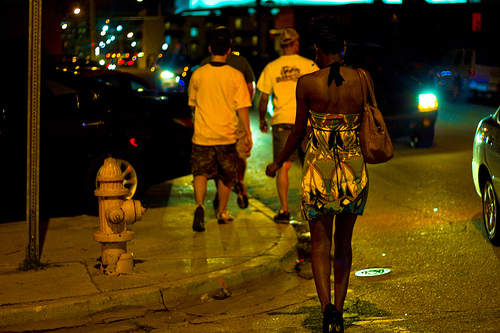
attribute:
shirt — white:
[183, 59, 251, 148]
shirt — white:
[256, 52, 323, 129]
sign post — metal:
[19, 10, 51, 267]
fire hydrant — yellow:
[92, 155, 144, 277]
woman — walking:
[245, 29, 446, 329]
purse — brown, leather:
[354, 65, 394, 165]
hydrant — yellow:
[94, 156, 148, 273]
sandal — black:
[192, 204, 204, 231]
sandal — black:
[215, 212, 235, 224]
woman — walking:
[263, 12, 376, 332]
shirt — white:
[185, 61, 270, 155]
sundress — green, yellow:
[283, 90, 392, 226]